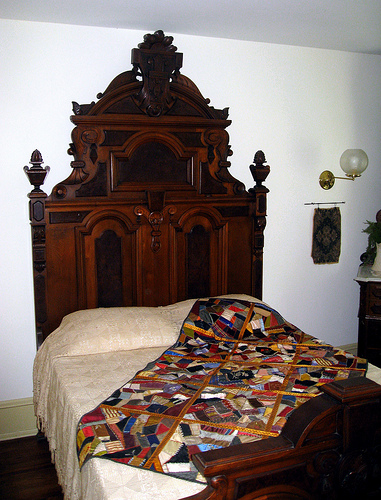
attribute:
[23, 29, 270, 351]
headboard — large, ornate, black, wooden, tall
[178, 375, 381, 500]
footboard — wooden, wood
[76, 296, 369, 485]
quilt — colorful, colored, square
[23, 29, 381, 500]
bed — made, well spread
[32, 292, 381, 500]
bedspread — white, silver color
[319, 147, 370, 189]
wall lamp — gold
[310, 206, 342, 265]
material — hanging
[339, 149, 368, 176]
glass — circular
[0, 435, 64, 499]
carpet — dark grey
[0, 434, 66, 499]
floor — wooden, brown, dark wood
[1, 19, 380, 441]
wall — white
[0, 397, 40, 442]
baseboard — cream, beige